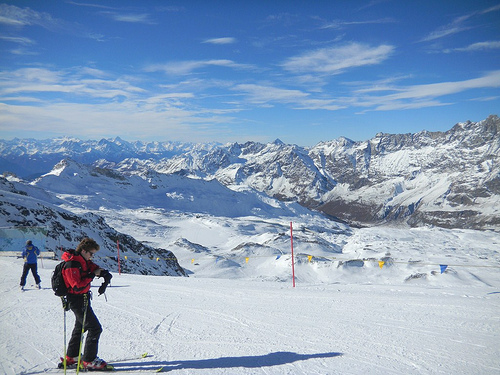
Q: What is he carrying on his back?
A: Backpack.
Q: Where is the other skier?
A: Down the slope.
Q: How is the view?
A: Beautiful.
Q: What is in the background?
A: Mountains.